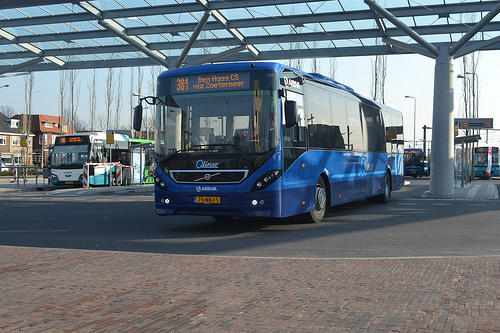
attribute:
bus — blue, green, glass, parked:
[127, 39, 395, 228]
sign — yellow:
[171, 61, 253, 109]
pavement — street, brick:
[111, 225, 267, 292]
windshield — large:
[146, 89, 283, 161]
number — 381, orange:
[161, 66, 209, 98]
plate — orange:
[183, 189, 231, 207]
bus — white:
[43, 100, 140, 213]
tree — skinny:
[78, 64, 138, 131]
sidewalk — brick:
[2, 173, 103, 256]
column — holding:
[396, 36, 492, 200]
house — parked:
[0, 117, 78, 180]